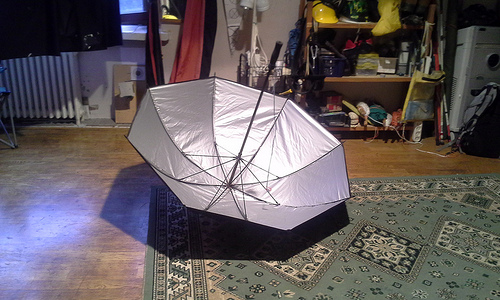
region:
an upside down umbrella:
[125, 39, 353, 233]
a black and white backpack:
[456, 80, 498, 160]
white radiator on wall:
[0, 51, 87, 126]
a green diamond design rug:
[139, 171, 499, 298]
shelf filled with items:
[296, 0, 444, 140]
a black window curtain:
[0, 0, 125, 61]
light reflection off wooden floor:
[0, 170, 94, 298]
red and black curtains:
[144, 0, 216, 83]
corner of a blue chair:
[0, 61, 22, 151]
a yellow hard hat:
[309, 0, 341, 28]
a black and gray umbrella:
[122, 37, 359, 237]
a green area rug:
[144, 176, 499, 298]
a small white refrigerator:
[446, 26, 498, 140]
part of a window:
[114, 0, 144, 20]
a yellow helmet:
[309, 2, 339, 24]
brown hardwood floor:
[336, 136, 498, 176]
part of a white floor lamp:
[239, 0, 274, 85]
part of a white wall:
[212, 9, 242, 79]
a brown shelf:
[306, 1, 436, 142]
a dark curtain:
[0, 0, 123, 61]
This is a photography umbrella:
[60, 27, 382, 239]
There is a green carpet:
[133, 129, 485, 298]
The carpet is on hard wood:
[145, 182, 488, 298]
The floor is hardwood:
[5, 102, 147, 298]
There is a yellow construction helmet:
[312, 0, 343, 35]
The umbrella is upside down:
[125, 47, 362, 234]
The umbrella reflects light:
[140, 65, 344, 237]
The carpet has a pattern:
[182, 167, 495, 299]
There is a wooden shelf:
[290, 1, 447, 175]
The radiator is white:
[1, 24, 96, 134]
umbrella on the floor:
[28, 11, 349, 238]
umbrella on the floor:
[162, 67, 346, 269]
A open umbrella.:
[122, 50, 361, 235]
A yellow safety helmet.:
[310, 0, 344, 24]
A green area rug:
[132, 181, 498, 298]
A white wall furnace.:
[4, 52, 90, 125]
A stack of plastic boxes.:
[357, 53, 378, 78]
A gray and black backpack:
[457, 85, 498, 156]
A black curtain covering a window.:
[3, 3, 128, 56]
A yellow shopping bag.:
[370, 2, 404, 39]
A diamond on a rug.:
[338, 219, 445, 285]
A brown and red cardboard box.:
[325, 92, 345, 111]